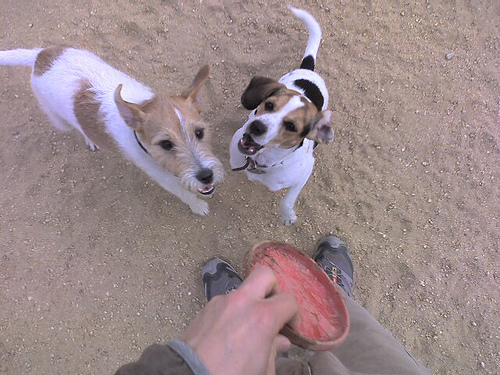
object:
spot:
[65, 81, 120, 159]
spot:
[26, 40, 72, 79]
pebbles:
[49, 249, 85, 275]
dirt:
[0, 106, 36, 270]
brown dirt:
[351, 0, 498, 265]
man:
[98, 231, 446, 374]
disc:
[233, 234, 355, 350]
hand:
[175, 259, 304, 375]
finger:
[234, 257, 279, 298]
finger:
[267, 290, 303, 330]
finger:
[266, 330, 292, 374]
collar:
[243, 155, 271, 176]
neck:
[264, 142, 306, 173]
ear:
[108, 75, 144, 132]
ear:
[177, 62, 217, 117]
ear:
[234, 72, 284, 112]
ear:
[305, 105, 338, 149]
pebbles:
[428, 35, 463, 76]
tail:
[282, 2, 325, 72]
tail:
[0, 42, 40, 67]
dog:
[0, 39, 222, 215]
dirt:
[0, 0, 280, 43]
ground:
[426, 0, 500, 375]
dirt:
[314, 192, 356, 230]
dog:
[226, 2, 344, 229]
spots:
[290, 75, 330, 110]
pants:
[275, 282, 424, 375]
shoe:
[194, 252, 243, 302]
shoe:
[308, 234, 357, 298]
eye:
[154, 138, 173, 150]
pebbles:
[377, 220, 390, 247]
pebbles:
[92, 266, 118, 300]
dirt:
[402, 281, 500, 337]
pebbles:
[61, 282, 106, 301]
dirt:
[0, 176, 146, 338]